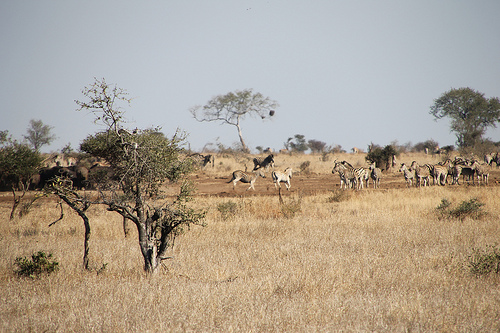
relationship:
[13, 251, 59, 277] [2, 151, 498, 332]
bush on ground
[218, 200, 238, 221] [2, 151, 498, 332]
bush on ground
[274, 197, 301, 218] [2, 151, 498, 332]
bush on ground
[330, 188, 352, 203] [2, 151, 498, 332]
bush on ground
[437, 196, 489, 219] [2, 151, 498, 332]
bush on ground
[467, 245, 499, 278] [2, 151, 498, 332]
bush on ground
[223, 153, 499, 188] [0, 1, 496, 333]
animals in plains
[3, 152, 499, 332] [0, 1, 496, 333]
brown grass in plains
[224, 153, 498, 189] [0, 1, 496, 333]
zebras in plains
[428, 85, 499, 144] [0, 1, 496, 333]
tree at edge of plains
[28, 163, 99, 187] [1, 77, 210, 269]
animals behind trees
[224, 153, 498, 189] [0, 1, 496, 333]
zebras running in plains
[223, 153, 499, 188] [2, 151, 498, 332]
animals on ground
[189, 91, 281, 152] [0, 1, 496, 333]
tree in plains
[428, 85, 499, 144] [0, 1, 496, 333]
tree in plains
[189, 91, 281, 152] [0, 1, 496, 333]
tree on plains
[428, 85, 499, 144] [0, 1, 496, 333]
tree on plains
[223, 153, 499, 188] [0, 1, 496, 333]
animals on plains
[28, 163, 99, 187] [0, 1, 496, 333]
animals on plains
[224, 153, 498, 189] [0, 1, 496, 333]
zebras on plains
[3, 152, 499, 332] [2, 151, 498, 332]
brown grass on ground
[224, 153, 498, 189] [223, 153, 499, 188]
zebras are in a group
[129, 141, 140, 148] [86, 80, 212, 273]
nest in tree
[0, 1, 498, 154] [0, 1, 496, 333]
sky over plains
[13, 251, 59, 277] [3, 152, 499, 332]
bush in brown grass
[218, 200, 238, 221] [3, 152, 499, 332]
bush in brown grass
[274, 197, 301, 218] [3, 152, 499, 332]
bush in brown grass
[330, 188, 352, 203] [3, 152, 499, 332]
bush in brown grass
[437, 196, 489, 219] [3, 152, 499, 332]
bush in brown grass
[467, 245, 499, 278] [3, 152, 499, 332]
bush in brown grass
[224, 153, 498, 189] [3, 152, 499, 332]
zebras on brown grass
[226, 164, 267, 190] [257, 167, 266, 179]
zebra has a head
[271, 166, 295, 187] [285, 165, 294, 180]
zebra has a head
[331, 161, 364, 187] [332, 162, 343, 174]
zebra has a head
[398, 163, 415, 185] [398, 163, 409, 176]
zebra has a head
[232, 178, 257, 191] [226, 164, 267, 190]
legs of a zebra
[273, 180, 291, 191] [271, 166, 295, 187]
legs of a zebra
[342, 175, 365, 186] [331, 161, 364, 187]
legs of a zebra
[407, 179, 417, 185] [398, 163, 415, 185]
legs of a zebra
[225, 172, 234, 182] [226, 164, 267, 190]
tail of a zebra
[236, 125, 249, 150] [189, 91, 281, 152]
trunk of a tree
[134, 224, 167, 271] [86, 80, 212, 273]
trunk of a tree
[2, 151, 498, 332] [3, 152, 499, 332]
ground has brown grass